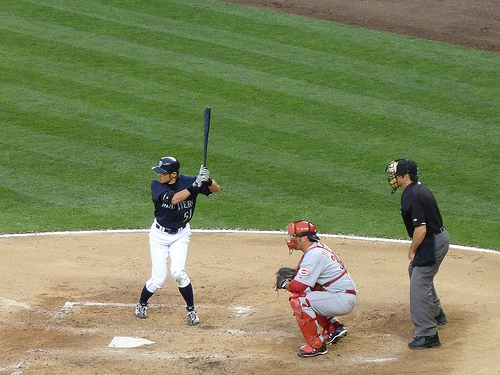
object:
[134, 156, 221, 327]
batter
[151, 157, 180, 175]
helmet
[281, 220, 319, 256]
helmet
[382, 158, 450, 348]
umpire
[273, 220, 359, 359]
catcher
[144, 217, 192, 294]
pants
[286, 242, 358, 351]
uniform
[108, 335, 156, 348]
plate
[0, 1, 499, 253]
field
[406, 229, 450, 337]
pants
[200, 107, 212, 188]
bat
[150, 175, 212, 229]
shirt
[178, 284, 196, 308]
sock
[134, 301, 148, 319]
shoe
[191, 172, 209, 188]
gloves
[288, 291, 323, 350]
pad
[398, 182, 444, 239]
shirt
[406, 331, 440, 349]
shoe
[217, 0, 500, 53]
dirt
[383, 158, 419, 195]
helmet